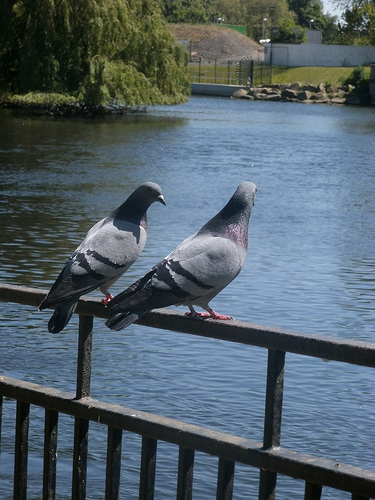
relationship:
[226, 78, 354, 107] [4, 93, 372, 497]
rock pile across water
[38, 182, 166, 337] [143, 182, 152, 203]
bird has eye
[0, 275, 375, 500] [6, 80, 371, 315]
rail next lake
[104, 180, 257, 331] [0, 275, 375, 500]
pigeon sitting rail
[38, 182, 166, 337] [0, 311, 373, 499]
bird on railing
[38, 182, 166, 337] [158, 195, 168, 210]
bird has a beak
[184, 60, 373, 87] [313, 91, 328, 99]
hill behind rock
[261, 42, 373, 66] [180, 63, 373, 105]
white wall behind hill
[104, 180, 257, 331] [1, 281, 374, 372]
pigeon standing on railing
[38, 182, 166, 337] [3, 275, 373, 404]
bird standing on metal rail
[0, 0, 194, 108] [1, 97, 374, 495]
trees next to lake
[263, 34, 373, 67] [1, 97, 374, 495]
building next to lake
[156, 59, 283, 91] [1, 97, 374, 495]
fence near lake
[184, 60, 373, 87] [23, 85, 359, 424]
hill next to lake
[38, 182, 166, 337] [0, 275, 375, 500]
bird on rail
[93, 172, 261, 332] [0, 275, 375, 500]
pigeon on rail